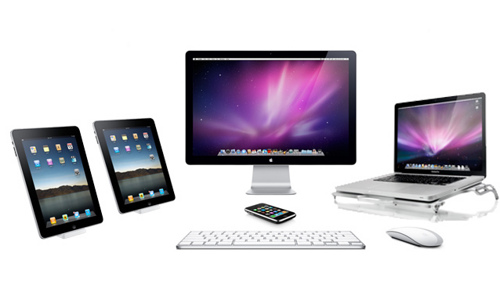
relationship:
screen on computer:
[189, 57, 354, 162] [183, 47, 360, 196]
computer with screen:
[182, 44, 360, 211] [184, 55, 356, 168]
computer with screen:
[338, 86, 498, 206] [392, 94, 485, 174]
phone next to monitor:
[239, 200, 299, 222] [174, 40, 365, 173]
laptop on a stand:
[333, 86, 499, 209] [353, 164, 485, 235]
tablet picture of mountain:
[1, 116, 103, 252] [37, 177, 80, 195]